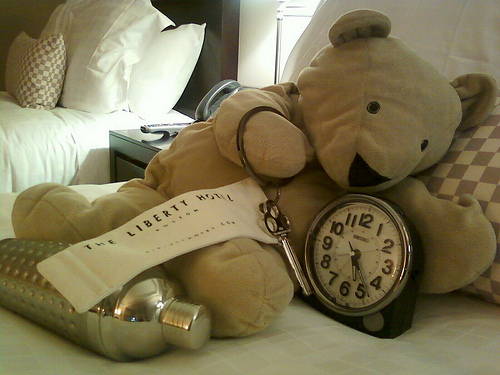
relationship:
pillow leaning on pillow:
[3, 30, 66, 110] [40, 1, 175, 113]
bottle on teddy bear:
[0, 230, 216, 365] [26, 10, 498, 312]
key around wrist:
[246, 187, 309, 309] [229, 92, 312, 195]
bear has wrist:
[5, 6, 499, 342] [229, 92, 312, 195]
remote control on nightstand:
[135, 113, 212, 139] [97, 115, 286, 195]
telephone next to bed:
[196, 85, 237, 118] [1, 1, 244, 246]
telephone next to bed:
[196, 85, 237, 118] [4, 0, 484, 370]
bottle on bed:
[1, 232, 216, 368] [0, 10, 205, 175]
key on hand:
[252, 196, 318, 298] [227, 102, 316, 185]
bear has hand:
[19, 14, 493, 319] [227, 102, 316, 185]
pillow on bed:
[3, 30, 70, 110] [2, 98, 208, 202]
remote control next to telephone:
[135, 113, 203, 136] [193, 77, 263, 127]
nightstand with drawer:
[108, 128, 176, 180] [111, 135, 156, 184]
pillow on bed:
[133, 19, 210, 120] [2, 33, 217, 192]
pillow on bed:
[47, 7, 172, 111] [2, 33, 217, 192]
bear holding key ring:
[5, 6, 499, 342] [254, 187, 311, 311]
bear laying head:
[5, 6, 499, 342] [293, 6, 499, 196]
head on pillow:
[293, 6, 499, 196] [411, 91, 498, 307]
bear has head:
[5, 6, 499, 342] [293, 6, 499, 196]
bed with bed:
[0, 0, 241, 196] [0, 0, 241, 196]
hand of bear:
[227, 102, 316, 185] [184, 46, 488, 223]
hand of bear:
[385, 179, 498, 296] [19, 14, 493, 319]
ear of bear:
[326, 13, 396, 53] [19, 14, 493, 319]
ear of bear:
[326, 6, 396, 49] [19, 14, 493, 319]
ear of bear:
[448, 74, 498, 129] [19, 14, 493, 319]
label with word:
[43, 187, 281, 289] [78, 235, 117, 250]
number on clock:
[369, 272, 387, 292] [295, 187, 427, 328]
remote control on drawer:
[135, 113, 212, 139] [114, 135, 176, 170]